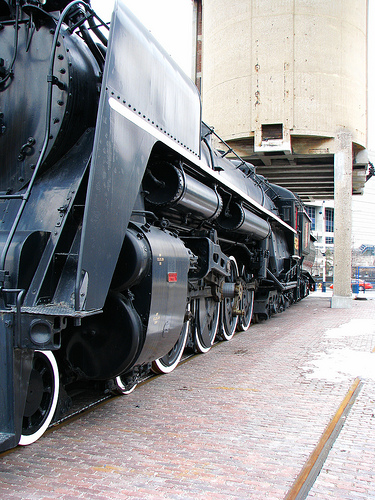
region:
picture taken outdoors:
[59, 217, 365, 448]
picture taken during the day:
[79, 214, 373, 442]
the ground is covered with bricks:
[60, 185, 295, 498]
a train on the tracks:
[51, 231, 276, 454]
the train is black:
[43, 194, 294, 277]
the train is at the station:
[72, 200, 364, 447]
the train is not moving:
[77, 303, 292, 431]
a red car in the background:
[315, 221, 372, 341]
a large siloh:
[270, 165, 370, 218]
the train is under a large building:
[200, 59, 343, 139]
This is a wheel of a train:
[1, 331, 65, 451]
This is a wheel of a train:
[109, 298, 147, 397]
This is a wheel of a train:
[140, 288, 193, 383]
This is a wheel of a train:
[190, 282, 221, 356]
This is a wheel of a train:
[217, 272, 240, 347]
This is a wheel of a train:
[239, 276, 257, 330]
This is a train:
[6, 3, 324, 447]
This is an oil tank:
[145, 147, 227, 231]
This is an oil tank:
[225, 188, 276, 248]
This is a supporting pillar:
[322, 128, 368, 313]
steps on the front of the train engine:
[44, 162, 106, 312]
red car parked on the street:
[331, 276, 372, 293]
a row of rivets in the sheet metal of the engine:
[104, 80, 202, 158]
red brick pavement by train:
[93, 406, 260, 475]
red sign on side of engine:
[164, 265, 180, 285]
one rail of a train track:
[285, 394, 353, 484]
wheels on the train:
[193, 287, 254, 340]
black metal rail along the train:
[199, 115, 262, 181]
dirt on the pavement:
[320, 346, 366, 380]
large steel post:
[320, 141, 357, 309]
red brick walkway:
[177, 326, 342, 498]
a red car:
[327, 274, 374, 292]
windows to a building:
[322, 206, 338, 234]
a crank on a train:
[215, 278, 251, 318]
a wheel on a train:
[190, 272, 221, 350]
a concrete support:
[326, 156, 358, 310]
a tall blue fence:
[350, 264, 374, 303]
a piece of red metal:
[164, 270, 179, 283]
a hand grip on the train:
[13, 135, 41, 157]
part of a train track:
[74, 400, 102, 415]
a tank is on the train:
[153, 164, 223, 222]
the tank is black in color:
[163, 164, 224, 220]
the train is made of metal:
[3, 2, 310, 438]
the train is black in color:
[1, 1, 315, 434]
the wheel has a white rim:
[14, 343, 59, 446]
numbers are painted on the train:
[292, 236, 302, 254]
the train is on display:
[0, 1, 322, 418]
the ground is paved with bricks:
[6, 292, 374, 498]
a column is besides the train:
[330, 133, 354, 309]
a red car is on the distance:
[328, 277, 371, 291]